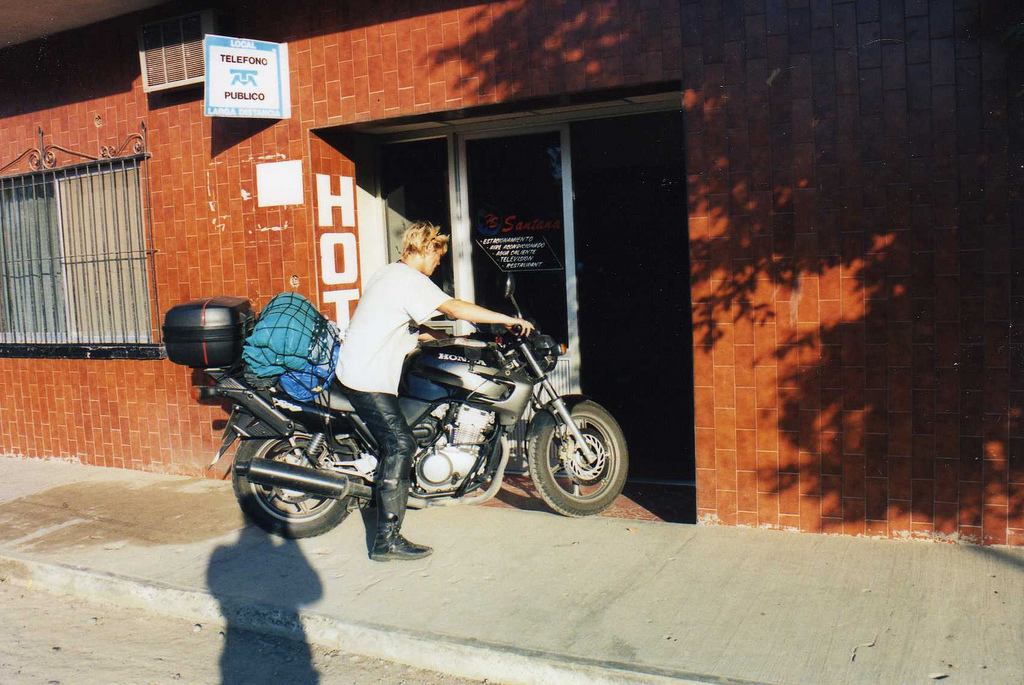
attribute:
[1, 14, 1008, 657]
building — red, brick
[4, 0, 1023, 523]
building — brick